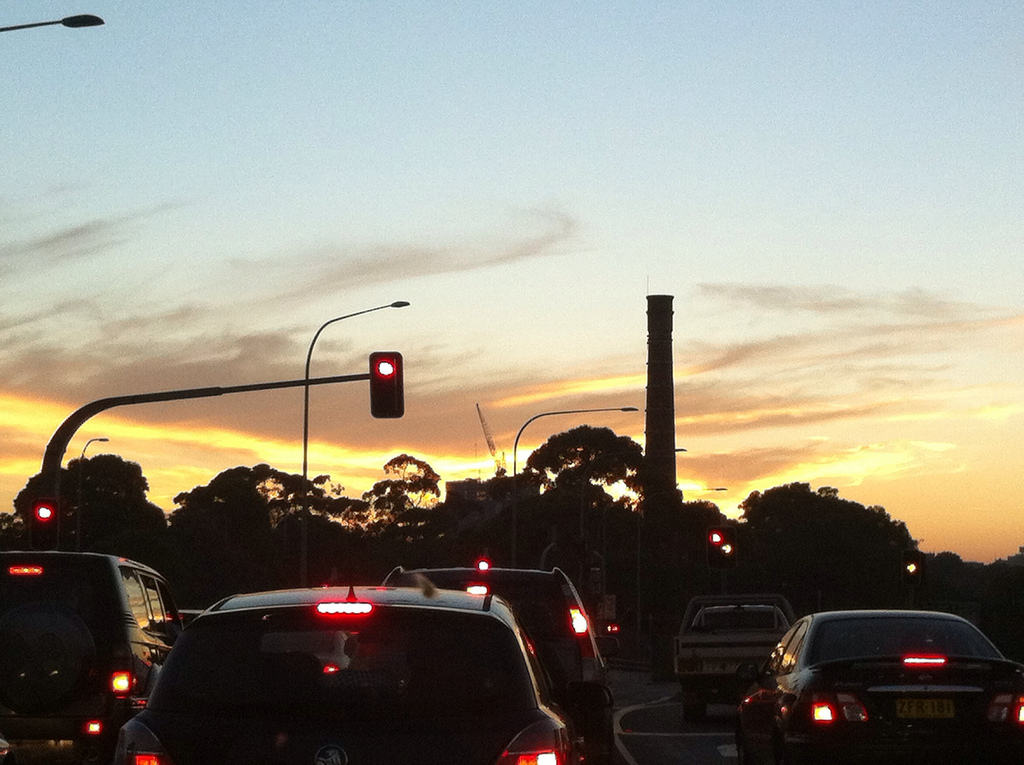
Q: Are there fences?
A: No, there are no fences.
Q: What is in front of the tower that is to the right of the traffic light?
A: The trees are in front of the tower.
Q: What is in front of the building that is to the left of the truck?
A: The trees are in front of the tower.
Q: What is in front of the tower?
A: The trees are in front of the tower.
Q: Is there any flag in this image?
A: No, there are no flags.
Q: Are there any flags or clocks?
A: No, there are no flags or clocks.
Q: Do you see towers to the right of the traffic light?
A: Yes, there is a tower to the right of the traffic light.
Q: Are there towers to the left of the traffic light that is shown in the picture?
A: No, the tower is to the right of the traffic light.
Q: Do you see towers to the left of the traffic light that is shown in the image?
A: No, the tower is to the right of the traffic light.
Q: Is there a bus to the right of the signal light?
A: No, there is a tower to the right of the signal light.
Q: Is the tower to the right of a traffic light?
A: Yes, the tower is to the right of a traffic light.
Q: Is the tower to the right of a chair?
A: No, the tower is to the right of a traffic light.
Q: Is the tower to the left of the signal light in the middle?
A: No, the tower is to the right of the traffic signal.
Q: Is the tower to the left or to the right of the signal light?
A: The tower is to the right of the signal light.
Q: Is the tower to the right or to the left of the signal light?
A: The tower is to the right of the signal light.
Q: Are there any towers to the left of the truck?
A: Yes, there is a tower to the left of the truck.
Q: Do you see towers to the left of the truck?
A: Yes, there is a tower to the left of the truck.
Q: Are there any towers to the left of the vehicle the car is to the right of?
A: Yes, there is a tower to the left of the truck.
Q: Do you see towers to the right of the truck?
A: No, the tower is to the left of the truck.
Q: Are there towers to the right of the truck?
A: No, the tower is to the left of the truck.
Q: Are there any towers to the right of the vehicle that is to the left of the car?
A: No, the tower is to the left of the truck.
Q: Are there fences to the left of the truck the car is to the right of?
A: No, there is a tower to the left of the truck.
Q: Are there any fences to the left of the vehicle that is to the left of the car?
A: No, there is a tower to the left of the truck.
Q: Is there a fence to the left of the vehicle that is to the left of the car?
A: No, there is a tower to the left of the truck.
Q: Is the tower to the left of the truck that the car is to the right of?
A: Yes, the tower is to the left of the truck.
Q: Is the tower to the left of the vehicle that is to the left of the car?
A: Yes, the tower is to the left of the truck.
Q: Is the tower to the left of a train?
A: No, the tower is to the left of the truck.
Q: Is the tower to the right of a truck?
A: No, the tower is to the left of a truck.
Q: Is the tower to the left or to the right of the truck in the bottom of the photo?
A: The tower is to the left of the truck.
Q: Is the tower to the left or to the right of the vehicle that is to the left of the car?
A: The tower is to the left of the truck.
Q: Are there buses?
A: No, there are no buses.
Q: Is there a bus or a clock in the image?
A: No, there are no buses or clocks.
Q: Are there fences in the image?
A: No, there are no fences.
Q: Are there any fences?
A: No, there are no fences.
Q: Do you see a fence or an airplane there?
A: No, there are no fences or airplanes.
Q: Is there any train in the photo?
A: No, there are no trains.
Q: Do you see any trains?
A: No, there are no trains.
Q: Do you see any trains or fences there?
A: No, there are no trains or fences.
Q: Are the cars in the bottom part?
A: Yes, the cars are in the bottom of the image.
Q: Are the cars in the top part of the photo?
A: No, the cars are in the bottom of the image.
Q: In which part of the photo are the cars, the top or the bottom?
A: The cars are in the bottom of the image.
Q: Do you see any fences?
A: No, there are no fences.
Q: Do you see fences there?
A: No, there are no fences.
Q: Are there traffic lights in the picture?
A: Yes, there is a traffic light.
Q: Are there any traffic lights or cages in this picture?
A: Yes, there is a traffic light.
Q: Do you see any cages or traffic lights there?
A: Yes, there is a traffic light.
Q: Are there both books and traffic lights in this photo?
A: No, there is a traffic light but no books.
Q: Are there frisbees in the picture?
A: No, there are no frisbees.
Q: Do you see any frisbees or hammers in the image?
A: No, there are no frisbees or hammers.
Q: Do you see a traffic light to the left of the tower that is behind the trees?
A: Yes, there is a traffic light to the left of the tower.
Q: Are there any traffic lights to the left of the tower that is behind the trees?
A: Yes, there is a traffic light to the left of the tower.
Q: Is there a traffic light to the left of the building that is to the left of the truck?
A: Yes, there is a traffic light to the left of the tower.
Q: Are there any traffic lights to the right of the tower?
A: No, the traffic light is to the left of the tower.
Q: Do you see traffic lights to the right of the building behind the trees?
A: No, the traffic light is to the left of the tower.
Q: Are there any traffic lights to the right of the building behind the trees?
A: No, the traffic light is to the left of the tower.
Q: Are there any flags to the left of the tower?
A: No, there is a traffic light to the left of the tower.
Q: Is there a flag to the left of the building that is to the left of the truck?
A: No, there is a traffic light to the left of the tower.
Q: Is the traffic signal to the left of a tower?
A: Yes, the traffic signal is to the left of a tower.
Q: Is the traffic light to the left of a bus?
A: No, the traffic light is to the left of a tower.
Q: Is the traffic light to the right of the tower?
A: No, the traffic light is to the left of the tower.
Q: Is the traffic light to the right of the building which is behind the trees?
A: No, the traffic light is to the left of the tower.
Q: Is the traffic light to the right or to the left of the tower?
A: The traffic light is to the left of the tower.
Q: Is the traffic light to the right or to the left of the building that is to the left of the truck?
A: The traffic light is to the left of the tower.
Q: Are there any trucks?
A: Yes, there is a truck.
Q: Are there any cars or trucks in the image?
A: Yes, there is a truck.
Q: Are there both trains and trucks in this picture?
A: No, there is a truck but no trains.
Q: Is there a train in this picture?
A: No, there are no trains.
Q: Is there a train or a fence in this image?
A: No, there are no trains or fences.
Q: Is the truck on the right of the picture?
A: Yes, the truck is on the right of the image.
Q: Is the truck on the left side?
A: No, the truck is on the right of the image.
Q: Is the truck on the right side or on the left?
A: The truck is on the right of the image.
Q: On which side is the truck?
A: The truck is on the right of the image.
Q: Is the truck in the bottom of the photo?
A: Yes, the truck is in the bottom of the image.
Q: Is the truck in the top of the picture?
A: No, the truck is in the bottom of the image.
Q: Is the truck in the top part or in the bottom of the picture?
A: The truck is in the bottom of the image.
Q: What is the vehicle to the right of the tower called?
A: The vehicle is a truck.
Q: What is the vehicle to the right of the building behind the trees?
A: The vehicle is a truck.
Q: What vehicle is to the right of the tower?
A: The vehicle is a truck.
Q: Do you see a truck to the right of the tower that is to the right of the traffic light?
A: Yes, there is a truck to the right of the tower.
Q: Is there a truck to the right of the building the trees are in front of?
A: Yes, there is a truck to the right of the tower.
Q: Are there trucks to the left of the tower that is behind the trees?
A: No, the truck is to the right of the tower.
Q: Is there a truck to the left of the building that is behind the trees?
A: No, the truck is to the right of the tower.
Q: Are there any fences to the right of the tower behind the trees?
A: No, there is a truck to the right of the tower.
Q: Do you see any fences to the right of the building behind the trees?
A: No, there is a truck to the right of the tower.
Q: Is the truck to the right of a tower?
A: Yes, the truck is to the right of a tower.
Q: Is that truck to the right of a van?
A: No, the truck is to the right of a tower.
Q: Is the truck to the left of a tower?
A: No, the truck is to the right of a tower.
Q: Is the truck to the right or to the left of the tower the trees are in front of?
A: The truck is to the right of the tower.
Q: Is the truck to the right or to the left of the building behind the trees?
A: The truck is to the right of the tower.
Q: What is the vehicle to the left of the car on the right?
A: The vehicle is a truck.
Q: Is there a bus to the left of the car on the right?
A: No, there is a truck to the left of the car.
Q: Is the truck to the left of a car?
A: Yes, the truck is to the left of a car.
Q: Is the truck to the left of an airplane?
A: No, the truck is to the left of a car.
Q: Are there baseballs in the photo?
A: No, there are no baseballs.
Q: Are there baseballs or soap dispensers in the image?
A: No, there are no baseballs or soap dispensers.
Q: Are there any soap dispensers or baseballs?
A: No, there are no baseballs or soap dispensers.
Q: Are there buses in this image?
A: No, there are no buses.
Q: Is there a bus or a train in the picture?
A: No, there are no buses or trains.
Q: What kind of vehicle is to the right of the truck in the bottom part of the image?
A: The vehicle is a car.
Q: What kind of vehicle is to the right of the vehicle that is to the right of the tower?
A: The vehicle is a car.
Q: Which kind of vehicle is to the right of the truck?
A: The vehicle is a car.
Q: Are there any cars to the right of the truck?
A: Yes, there is a car to the right of the truck.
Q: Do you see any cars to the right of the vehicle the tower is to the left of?
A: Yes, there is a car to the right of the truck.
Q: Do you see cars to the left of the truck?
A: No, the car is to the right of the truck.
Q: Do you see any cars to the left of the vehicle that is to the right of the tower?
A: No, the car is to the right of the truck.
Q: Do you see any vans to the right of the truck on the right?
A: No, there is a car to the right of the truck.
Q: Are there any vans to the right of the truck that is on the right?
A: No, there is a car to the right of the truck.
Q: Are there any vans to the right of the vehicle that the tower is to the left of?
A: No, there is a car to the right of the truck.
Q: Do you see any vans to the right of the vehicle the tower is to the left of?
A: No, there is a car to the right of the truck.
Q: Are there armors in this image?
A: No, there are no armors.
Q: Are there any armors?
A: No, there are no armors.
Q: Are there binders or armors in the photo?
A: No, there are no armors or binders.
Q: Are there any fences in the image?
A: No, there are no fences.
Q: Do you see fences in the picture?
A: No, there are no fences.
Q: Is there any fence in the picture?
A: No, there are no fences.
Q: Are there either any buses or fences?
A: No, there are no fences or buses.